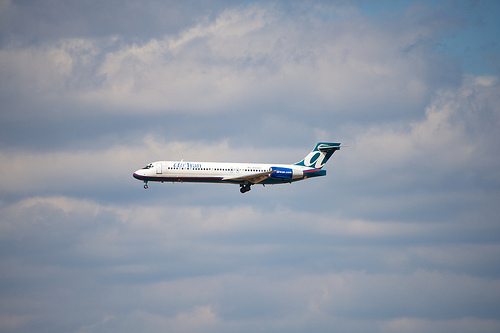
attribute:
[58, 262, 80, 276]
bird — Black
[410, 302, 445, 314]
bird — Black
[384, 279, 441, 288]
bird — Black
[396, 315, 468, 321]
bird — Black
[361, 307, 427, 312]
bird — Black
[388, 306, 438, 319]
bird — Black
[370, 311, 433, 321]
bird — Black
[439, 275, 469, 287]
bird — Black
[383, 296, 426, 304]
bird — Black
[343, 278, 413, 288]
bird — Black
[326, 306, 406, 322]
bird — Black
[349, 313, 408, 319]
bird — Black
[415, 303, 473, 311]
bird — Black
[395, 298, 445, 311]
bird — Black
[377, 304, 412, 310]
bird — Black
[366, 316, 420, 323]
bird — Black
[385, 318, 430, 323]
bird — Black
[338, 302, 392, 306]
bird — Black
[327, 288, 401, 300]
bird — Black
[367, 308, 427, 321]
bird — Black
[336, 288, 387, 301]
bird — Black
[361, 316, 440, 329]
bird — Black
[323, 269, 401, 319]
bird — Black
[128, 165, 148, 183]
nose — black, white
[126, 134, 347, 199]
jet engine — white, blue